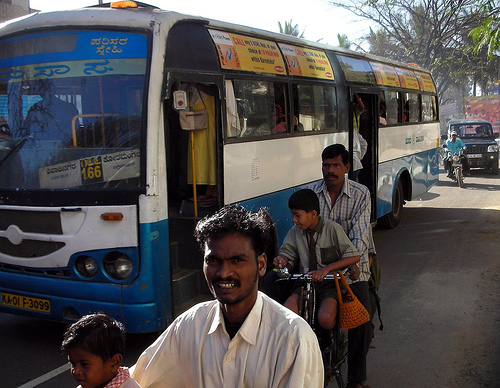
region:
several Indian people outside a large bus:
[2, 7, 456, 367]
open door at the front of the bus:
[156, 74, 228, 299]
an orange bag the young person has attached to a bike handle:
[325, 258, 375, 334]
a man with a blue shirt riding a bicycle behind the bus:
[444, 127, 467, 186]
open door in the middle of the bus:
[351, 89, 377, 219]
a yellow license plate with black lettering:
[2, 286, 53, 321]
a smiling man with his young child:
[37, 203, 330, 385]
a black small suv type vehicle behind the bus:
[447, 123, 498, 175]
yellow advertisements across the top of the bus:
[203, 25, 442, 93]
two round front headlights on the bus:
[60, 244, 142, 288]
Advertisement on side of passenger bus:
[207, 28, 289, 75]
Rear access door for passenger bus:
[347, 86, 384, 223]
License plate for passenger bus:
[0, 291, 54, 316]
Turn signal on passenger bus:
[96, 208, 127, 230]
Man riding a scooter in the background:
[442, 126, 472, 189]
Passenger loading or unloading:
[342, 91, 372, 217]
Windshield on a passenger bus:
[2, 31, 150, 191]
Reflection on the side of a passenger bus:
[382, 136, 434, 209]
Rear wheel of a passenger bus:
[380, 168, 405, 225]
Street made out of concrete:
[420, 192, 494, 377]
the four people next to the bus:
[57, 143, 382, 386]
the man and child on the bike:
[281, 144, 377, 384]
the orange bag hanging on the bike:
[333, 266, 371, 329]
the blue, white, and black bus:
[5, 2, 439, 328]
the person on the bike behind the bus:
[444, 131, 470, 188]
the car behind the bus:
[447, 116, 499, 170]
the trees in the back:
[332, 0, 498, 107]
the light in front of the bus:
[75, 247, 132, 281]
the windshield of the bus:
[1, 23, 148, 203]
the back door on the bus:
[346, 85, 376, 223]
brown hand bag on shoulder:
[170, 83, 217, 138]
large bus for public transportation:
[0, 6, 450, 319]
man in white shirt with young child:
[59, 205, 320, 385]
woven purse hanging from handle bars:
[325, 257, 379, 345]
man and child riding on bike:
[280, 140, 378, 387]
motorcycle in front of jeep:
[439, 113, 499, 180]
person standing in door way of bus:
[341, 83, 387, 217]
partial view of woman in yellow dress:
[167, 75, 224, 217]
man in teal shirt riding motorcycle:
[442, 123, 471, 193]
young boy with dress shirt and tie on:
[275, 185, 352, 335]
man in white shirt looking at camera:
[142, 204, 314, 385]